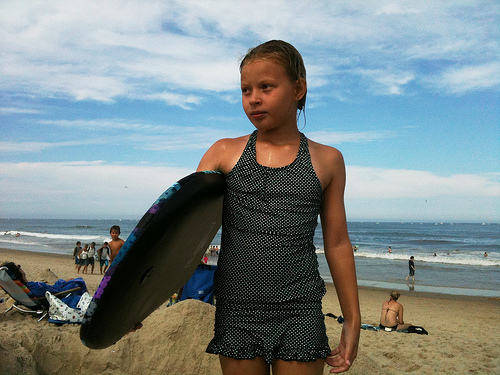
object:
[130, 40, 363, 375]
girl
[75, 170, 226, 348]
boogie board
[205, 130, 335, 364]
bathing suit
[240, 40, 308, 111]
hair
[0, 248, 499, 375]
sand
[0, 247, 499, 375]
beach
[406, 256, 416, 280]
person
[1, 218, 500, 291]
water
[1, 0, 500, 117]
clouds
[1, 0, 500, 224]
sky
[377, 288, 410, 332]
people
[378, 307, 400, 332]
bathing suit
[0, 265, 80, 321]
chair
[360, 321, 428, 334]
towel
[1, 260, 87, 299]
woman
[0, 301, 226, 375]
hole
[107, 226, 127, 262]
boy